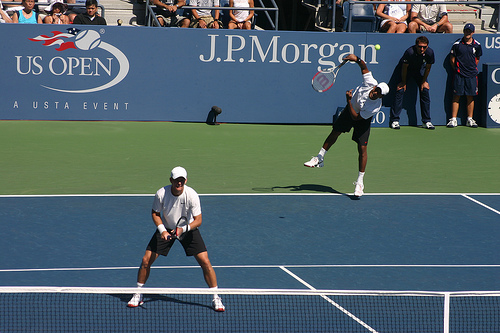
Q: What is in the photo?
A: A tennis court.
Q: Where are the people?
A: Tennis game.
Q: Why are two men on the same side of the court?
A: Team playing.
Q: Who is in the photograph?
A: Tennis players.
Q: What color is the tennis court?
A: Blue.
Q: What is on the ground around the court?
A: Turf.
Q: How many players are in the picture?
A: Two.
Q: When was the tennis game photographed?
A: Daytime.